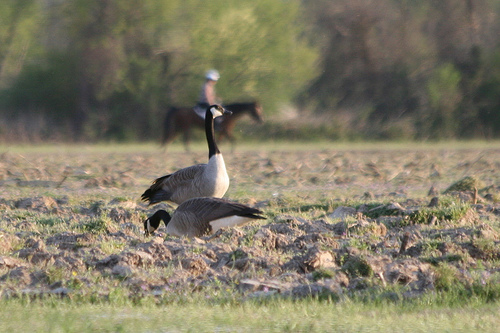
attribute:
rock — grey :
[292, 246, 329, 276]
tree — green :
[34, 29, 120, 145]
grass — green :
[3, 294, 480, 332]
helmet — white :
[202, 65, 222, 83]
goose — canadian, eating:
[157, 95, 254, 250]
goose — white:
[138, 106, 273, 231]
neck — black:
[190, 106, 228, 153]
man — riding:
[184, 70, 231, 103]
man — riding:
[186, 66, 236, 106]